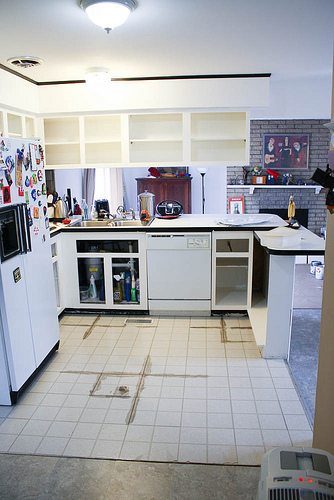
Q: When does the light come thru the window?
A: The daytime.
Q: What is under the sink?
A: Cleaning supplies.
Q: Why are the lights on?
A: It is night.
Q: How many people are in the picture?
A: Three.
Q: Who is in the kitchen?
A: No one.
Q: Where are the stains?
A: The floor.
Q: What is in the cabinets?
A: Nothing.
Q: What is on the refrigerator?
A: Magnets.